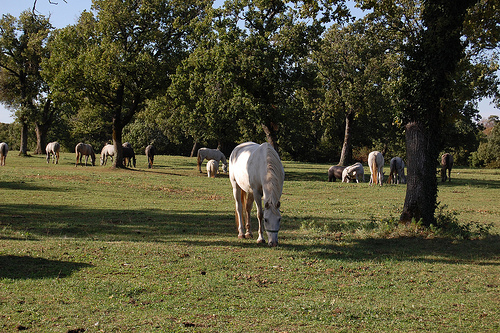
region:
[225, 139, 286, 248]
the horse is white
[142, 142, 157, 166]
a dark horse behind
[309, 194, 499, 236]
plants under a tree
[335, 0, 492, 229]
a tree beside the horse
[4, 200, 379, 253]
a shadow of a tree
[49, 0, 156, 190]
another large tree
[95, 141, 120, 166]
a horse behind the tree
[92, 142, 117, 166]
this horse is white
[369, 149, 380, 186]
this tail is red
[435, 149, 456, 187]
this horse is brown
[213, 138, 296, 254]
Tall horse in a field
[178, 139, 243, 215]
Tall horse in a field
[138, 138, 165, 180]
Tall horse in a field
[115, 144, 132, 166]
Tall horse in a field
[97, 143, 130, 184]
Tall horse in a field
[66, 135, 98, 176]
Tall horse in a field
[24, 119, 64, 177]
Tall horse in a field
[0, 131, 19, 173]
Tall horse in a field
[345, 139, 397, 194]
Tall horse in a field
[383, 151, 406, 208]
Tall horse in a field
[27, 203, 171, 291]
The grass is short and green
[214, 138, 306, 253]
The horse is grazing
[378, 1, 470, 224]
The tree trunk is the color brown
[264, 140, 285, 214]
The mane on the horse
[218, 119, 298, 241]
The color of the horse is white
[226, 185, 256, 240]
The back legs of the horse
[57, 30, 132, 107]
The leaves of the tree are green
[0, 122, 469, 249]
A large group of horses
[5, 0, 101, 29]
The sky is clear and blue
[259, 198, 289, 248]
The head of the horse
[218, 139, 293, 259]
white horse grazing by himself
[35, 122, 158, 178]
horses standing around tree on left side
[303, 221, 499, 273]
shadow of tree on the grass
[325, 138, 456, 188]
horses grazing around tree on the right side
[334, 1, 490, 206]
tree next to white horse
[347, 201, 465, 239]
weeds growing around tree trunk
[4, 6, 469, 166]
trees behind white horse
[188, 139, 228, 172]
white horses grazing under middle tree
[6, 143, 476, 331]
grass horses are grazing on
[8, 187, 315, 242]
shadow of tree behind white horse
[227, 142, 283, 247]
a white horse in field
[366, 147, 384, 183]
a white horse in field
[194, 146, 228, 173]
a white horse in field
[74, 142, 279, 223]
a white horse in field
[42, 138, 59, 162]
a white horse in field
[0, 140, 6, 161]
a white horse in field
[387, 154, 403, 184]
a white horse in field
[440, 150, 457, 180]
a brown horse in field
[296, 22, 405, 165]
large green tree in distance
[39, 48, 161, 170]
large green tree in distance